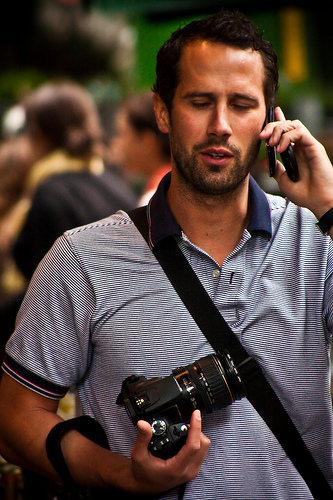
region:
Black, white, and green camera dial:
[146, 418, 168, 436]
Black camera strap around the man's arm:
[40, 413, 107, 489]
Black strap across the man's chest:
[115, 199, 331, 499]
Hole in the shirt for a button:
[223, 268, 242, 288]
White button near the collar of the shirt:
[206, 262, 225, 281]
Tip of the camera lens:
[220, 350, 248, 401]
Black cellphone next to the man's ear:
[267, 103, 302, 196]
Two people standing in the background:
[0, 50, 171, 240]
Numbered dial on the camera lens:
[195, 372, 219, 415]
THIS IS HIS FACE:
[148, 16, 280, 197]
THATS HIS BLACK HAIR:
[149, 12, 279, 100]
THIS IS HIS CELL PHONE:
[266, 106, 276, 184]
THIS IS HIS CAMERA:
[113, 349, 247, 463]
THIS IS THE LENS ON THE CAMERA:
[177, 347, 248, 418]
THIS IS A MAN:
[4, 16, 330, 495]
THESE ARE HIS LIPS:
[192, 146, 236, 166]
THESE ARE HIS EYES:
[187, 97, 257, 112]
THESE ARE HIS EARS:
[151, 91, 174, 134]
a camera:
[118, 357, 243, 414]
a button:
[211, 267, 218, 278]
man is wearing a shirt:
[110, 257, 156, 338]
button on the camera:
[152, 420, 165, 437]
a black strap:
[263, 397, 283, 426]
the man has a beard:
[214, 174, 229, 189]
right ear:
[151, 98, 169, 134]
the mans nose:
[211, 117, 231, 136]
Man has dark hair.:
[167, 19, 299, 59]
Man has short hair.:
[149, 22, 287, 56]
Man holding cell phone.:
[273, 131, 297, 172]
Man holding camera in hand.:
[117, 384, 209, 462]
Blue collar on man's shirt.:
[151, 212, 179, 250]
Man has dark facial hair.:
[176, 154, 205, 191]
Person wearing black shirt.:
[52, 194, 99, 232]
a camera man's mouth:
[199, 143, 239, 170]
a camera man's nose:
[207, 113, 237, 141]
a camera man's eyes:
[183, 88, 219, 110]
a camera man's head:
[167, 12, 274, 197]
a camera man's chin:
[190, 164, 238, 200]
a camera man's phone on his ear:
[267, 101, 296, 176]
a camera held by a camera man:
[121, 346, 262, 454]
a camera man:
[12, 38, 327, 448]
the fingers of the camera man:
[139, 421, 227, 464]